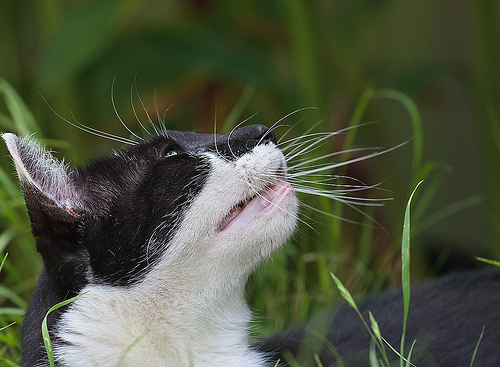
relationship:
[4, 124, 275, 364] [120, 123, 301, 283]
black fur on face